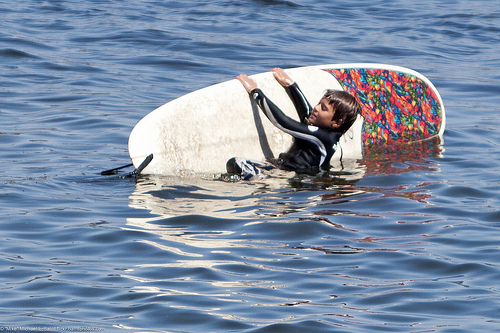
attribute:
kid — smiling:
[235, 65, 365, 167]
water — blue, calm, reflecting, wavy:
[3, 2, 499, 332]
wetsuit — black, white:
[249, 129, 334, 181]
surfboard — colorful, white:
[113, 62, 452, 161]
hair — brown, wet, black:
[321, 89, 358, 130]